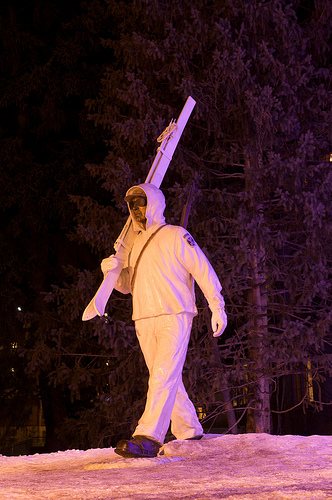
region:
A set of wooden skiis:
[60, 76, 213, 321]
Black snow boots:
[77, 409, 192, 471]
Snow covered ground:
[167, 429, 306, 497]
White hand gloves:
[200, 292, 242, 359]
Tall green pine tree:
[210, 37, 324, 418]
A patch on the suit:
[176, 215, 211, 265]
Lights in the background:
[1, 298, 39, 376]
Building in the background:
[187, 324, 325, 439]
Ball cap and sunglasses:
[100, 175, 183, 240]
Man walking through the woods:
[50, 197, 272, 487]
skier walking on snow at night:
[68, 64, 250, 471]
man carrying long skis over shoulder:
[71, 86, 232, 340]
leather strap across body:
[111, 213, 180, 301]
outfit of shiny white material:
[101, 224, 210, 423]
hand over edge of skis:
[94, 251, 124, 285]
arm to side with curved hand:
[175, 232, 239, 346]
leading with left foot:
[102, 304, 210, 471]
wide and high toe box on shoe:
[109, 421, 161, 455]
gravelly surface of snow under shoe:
[61, 443, 263, 487]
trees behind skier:
[127, 106, 305, 440]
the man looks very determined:
[79, 142, 239, 475]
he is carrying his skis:
[78, 35, 240, 424]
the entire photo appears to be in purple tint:
[51, 146, 308, 469]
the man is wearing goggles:
[111, 186, 184, 226]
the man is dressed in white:
[97, 168, 224, 472]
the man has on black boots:
[101, 421, 179, 468]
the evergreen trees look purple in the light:
[230, 196, 293, 432]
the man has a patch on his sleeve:
[161, 222, 221, 271]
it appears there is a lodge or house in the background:
[0, 323, 315, 446]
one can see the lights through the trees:
[189, 380, 236, 431]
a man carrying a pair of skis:
[61, 99, 272, 470]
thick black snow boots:
[112, 434, 161, 465]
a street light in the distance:
[10, 301, 33, 314]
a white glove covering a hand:
[203, 305, 235, 335]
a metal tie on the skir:
[157, 124, 182, 140]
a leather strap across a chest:
[143, 229, 158, 247]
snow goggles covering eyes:
[123, 196, 149, 208]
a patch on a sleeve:
[182, 227, 198, 249]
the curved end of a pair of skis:
[81, 288, 109, 323]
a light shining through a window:
[293, 363, 316, 411]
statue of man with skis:
[78, 97, 230, 423]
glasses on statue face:
[125, 193, 152, 215]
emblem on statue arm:
[180, 229, 198, 255]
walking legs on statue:
[120, 320, 203, 466]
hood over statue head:
[126, 177, 176, 232]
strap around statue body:
[121, 221, 173, 284]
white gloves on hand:
[203, 307, 241, 343]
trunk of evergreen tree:
[250, 371, 287, 430]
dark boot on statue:
[116, 433, 160, 459]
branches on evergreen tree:
[263, 181, 309, 234]